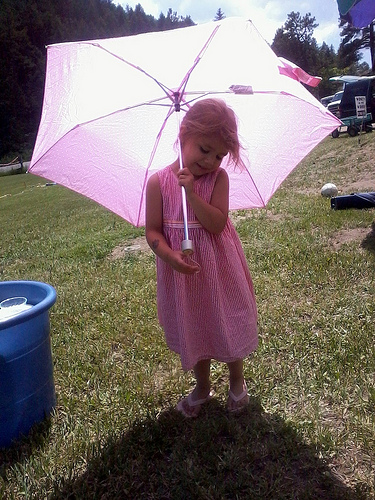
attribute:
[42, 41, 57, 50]
umbrella end — rounded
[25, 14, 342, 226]
umbrella — pink, opened up, open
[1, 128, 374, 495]
grass — an area, green, brown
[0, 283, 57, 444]
tub — big, plastic, large, blue, filled with liquid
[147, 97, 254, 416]
girl — little, child, light skinned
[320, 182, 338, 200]
soccer ball — white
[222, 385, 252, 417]
left flip flop — pink, light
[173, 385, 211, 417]
right flip flop — pink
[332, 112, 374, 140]
wagon — green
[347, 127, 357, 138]
wheel — black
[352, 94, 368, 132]
sign — tall, white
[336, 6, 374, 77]
tree — green leaved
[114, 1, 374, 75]
sky — overcast, blue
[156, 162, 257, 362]
sun dress — pink, white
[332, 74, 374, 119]
van — parked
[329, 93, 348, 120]
car — parked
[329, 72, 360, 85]
back door — open